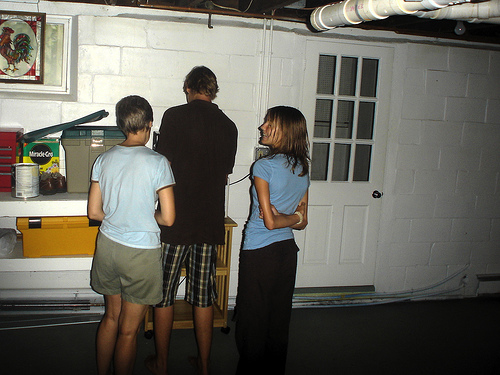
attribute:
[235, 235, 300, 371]
pants — black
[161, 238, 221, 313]
shorts — plaid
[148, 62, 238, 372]
man —  Young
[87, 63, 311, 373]
people — Three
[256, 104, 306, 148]
head —  woman's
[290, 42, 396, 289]
door —  white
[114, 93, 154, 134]
heads —  people's,  two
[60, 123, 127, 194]
container —  gray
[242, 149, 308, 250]
shirt —  Person's,  light blue ,  blue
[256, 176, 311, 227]
arms —  hers,  folded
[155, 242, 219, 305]
shorts —  plaid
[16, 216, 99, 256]
container —  yellow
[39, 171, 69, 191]
shoes —  brown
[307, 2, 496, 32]
pipe —  white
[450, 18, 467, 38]
light —  off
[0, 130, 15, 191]
toolbox —  red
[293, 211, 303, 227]
bracelet —  ARM's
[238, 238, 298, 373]
pants —  BLACK,  WOMAN's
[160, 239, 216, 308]
shorts —  MAN's,  PLAID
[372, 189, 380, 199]
knob —  DOOR's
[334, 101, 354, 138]
glass — in DOOR 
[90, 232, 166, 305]
shorts —  BROWN,  PERSON's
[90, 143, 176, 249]
shirt —  PERSON's,  LIGHT GREEN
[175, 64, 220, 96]
hair — brown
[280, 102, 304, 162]
hair — brown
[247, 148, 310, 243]
shirt — blue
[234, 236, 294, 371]
pants — black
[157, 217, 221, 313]
shorts — checked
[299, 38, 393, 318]
door — white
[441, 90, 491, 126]
brick — white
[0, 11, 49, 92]
painting — stained glass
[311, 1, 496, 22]
pipe — white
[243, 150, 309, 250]
t-shirt — blue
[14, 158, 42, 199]
can — Paint